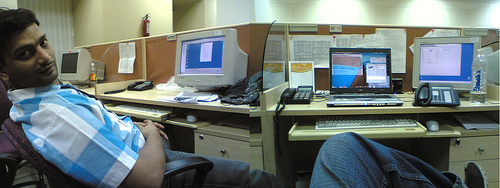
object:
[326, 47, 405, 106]
laptop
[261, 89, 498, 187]
desk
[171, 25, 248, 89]
computer monitor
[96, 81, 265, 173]
desk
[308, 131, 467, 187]
jeans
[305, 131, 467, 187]
leg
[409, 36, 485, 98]
computer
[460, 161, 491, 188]
shoe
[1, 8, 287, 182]
person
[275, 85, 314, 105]
telephone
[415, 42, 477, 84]
computer screen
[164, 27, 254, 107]
computer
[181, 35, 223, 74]
computer screen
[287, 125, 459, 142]
sliding tray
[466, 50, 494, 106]
water bottle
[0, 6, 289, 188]
person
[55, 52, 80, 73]
computer screen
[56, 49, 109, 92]
computer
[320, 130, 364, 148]
knee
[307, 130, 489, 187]
person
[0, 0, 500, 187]
office